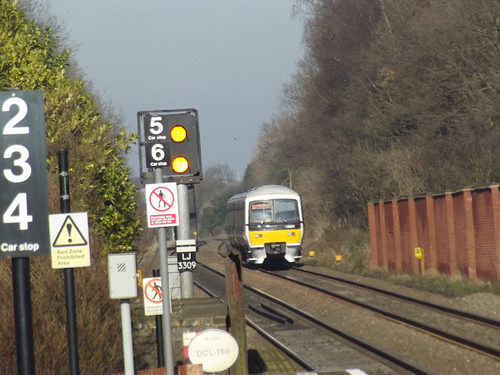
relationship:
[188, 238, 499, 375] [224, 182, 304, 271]
tracks under train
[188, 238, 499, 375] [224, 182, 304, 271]
tracks near train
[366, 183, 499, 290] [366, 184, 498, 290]
wall made of red bricks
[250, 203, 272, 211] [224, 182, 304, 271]
electric sign on train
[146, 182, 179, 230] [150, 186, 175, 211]
sign says no walking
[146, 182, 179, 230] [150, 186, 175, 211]
sign that says no walking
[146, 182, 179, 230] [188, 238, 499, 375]
sign near tracks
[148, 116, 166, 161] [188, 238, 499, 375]
56 near tracks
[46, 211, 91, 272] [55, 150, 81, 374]
sign on a black pole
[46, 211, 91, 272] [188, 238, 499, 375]
sign near tracks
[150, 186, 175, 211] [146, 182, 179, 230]
no walking on sign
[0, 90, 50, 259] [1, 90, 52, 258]
234 on sign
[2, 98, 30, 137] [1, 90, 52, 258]
2 on sign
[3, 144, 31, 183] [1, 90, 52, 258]
3 on sign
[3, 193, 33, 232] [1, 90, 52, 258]
4 on sign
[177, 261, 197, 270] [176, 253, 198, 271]
3309 on sign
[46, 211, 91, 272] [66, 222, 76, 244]
sign with exclamation point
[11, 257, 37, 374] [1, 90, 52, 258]
black pole holding up sign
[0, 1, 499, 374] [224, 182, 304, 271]
trees near train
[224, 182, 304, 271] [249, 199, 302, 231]
train has a windshield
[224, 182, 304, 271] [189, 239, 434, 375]
train on track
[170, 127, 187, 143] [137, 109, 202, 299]
light on post